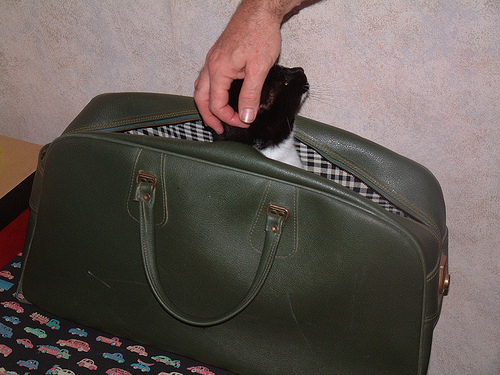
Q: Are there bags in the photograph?
A: Yes, there is a bag.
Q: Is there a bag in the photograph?
A: Yes, there is a bag.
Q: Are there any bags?
A: Yes, there is a bag.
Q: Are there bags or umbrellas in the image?
A: Yes, there is a bag.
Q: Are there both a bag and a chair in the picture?
A: No, there is a bag but no chairs.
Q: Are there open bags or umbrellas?
A: Yes, there is an open bag.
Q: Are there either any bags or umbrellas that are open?
A: Yes, the bag is open.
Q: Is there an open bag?
A: Yes, there is an open bag.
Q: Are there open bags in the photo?
A: Yes, there is an open bag.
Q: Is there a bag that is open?
A: Yes, there is a bag that is open.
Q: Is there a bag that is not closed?
A: Yes, there is a open bag.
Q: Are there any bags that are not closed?
A: Yes, there is a open bag.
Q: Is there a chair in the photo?
A: No, there are no chairs.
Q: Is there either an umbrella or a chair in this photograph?
A: No, there are no chairs or umbrellas.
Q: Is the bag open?
A: Yes, the bag is open.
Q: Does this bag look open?
A: Yes, the bag is open.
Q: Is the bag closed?
A: No, the bag is open.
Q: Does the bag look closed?
A: No, the bag is open.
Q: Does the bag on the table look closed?
A: No, the bag is open.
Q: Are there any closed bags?
A: No, there is a bag but it is open.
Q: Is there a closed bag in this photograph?
A: No, there is a bag but it is open.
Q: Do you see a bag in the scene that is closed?
A: No, there is a bag but it is open.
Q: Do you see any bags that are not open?
A: No, there is a bag but it is open.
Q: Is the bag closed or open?
A: The bag is open.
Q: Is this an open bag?
A: Yes, this is an open bag.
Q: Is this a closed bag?
A: No, this is an open bag.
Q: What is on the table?
A: The bag is on the table.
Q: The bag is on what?
A: The bag is on the table.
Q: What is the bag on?
A: The bag is on the table.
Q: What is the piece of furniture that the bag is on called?
A: The piece of furniture is a table.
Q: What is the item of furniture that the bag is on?
A: The piece of furniture is a table.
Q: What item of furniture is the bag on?
A: The bag is on the table.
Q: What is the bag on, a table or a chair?
A: The bag is on a table.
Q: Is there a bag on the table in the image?
A: Yes, there is a bag on the table.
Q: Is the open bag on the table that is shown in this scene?
A: Yes, the bag is on the table.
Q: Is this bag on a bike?
A: No, the bag is on the table.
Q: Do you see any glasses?
A: No, there are no glasses.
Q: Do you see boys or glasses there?
A: No, there are no glasses or boys.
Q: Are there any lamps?
A: No, there are no lamps.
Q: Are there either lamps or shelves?
A: No, there are no lamps or shelves.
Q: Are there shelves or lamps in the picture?
A: No, there are no lamps or shelves.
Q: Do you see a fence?
A: No, there are no fences.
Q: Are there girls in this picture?
A: No, there are no girls.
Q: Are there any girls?
A: No, there are no girls.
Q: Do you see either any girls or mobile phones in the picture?
A: No, there are no girls or mobile phones.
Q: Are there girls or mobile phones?
A: No, there are no girls or mobile phones.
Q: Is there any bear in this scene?
A: No, there are no bears.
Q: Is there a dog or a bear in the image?
A: No, there are no bears or dogs.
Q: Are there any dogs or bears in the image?
A: No, there are no bears or dogs.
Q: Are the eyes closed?
A: Yes, the eyes are closed.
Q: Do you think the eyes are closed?
A: Yes, the eyes are closed.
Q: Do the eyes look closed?
A: Yes, the eyes are closed.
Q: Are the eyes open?
A: No, the eyes are closed.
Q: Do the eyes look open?
A: No, the eyes are closed.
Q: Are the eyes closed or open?
A: The eyes are closed.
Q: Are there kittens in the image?
A: Yes, there is a kitten.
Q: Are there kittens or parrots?
A: Yes, there is a kitten.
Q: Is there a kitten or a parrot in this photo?
A: Yes, there is a kitten.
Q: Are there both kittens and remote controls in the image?
A: No, there is a kitten but no remote controls.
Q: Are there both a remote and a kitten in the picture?
A: No, there is a kitten but no remote controls.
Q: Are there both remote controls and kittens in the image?
A: No, there is a kitten but no remote controls.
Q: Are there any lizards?
A: No, there are no lizards.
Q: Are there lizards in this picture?
A: No, there are no lizards.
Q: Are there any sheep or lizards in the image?
A: No, there are no lizards or sheep.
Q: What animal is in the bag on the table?
A: The kitten is in the bag.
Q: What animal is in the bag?
A: The kitten is in the bag.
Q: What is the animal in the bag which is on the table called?
A: The animal is a kitten.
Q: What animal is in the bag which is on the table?
A: The animal is a kitten.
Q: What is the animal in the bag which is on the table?
A: The animal is a kitten.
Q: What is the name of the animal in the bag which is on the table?
A: The animal is a kitten.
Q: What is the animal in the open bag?
A: The animal is a kitten.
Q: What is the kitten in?
A: The kitten is in the bag.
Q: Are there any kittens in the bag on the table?
A: Yes, there is a kitten in the bag.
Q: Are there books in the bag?
A: No, there is a kitten in the bag.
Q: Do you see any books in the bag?
A: No, there is a kitten in the bag.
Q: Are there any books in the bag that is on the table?
A: No, there is a kitten in the bag.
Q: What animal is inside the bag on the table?
A: The kitten is inside the bag.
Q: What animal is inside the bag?
A: The kitten is inside the bag.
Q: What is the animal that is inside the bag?
A: The animal is a kitten.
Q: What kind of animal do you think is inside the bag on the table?
A: The animal is a kitten.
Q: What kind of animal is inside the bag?
A: The animal is a kitten.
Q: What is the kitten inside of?
A: The kitten is inside the bag.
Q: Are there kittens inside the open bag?
A: Yes, there is a kitten inside the bag.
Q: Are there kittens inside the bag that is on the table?
A: Yes, there is a kitten inside the bag.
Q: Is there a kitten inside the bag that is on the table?
A: Yes, there is a kitten inside the bag.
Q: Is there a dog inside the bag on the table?
A: No, there is a kitten inside the bag.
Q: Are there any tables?
A: Yes, there is a table.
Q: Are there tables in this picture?
A: Yes, there is a table.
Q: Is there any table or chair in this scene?
A: Yes, there is a table.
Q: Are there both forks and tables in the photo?
A: No, there is a table but no forks.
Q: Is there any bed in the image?
A: No, there are no beds.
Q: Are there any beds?
A: No, there are no beds.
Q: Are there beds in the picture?
A: No, there are no beds.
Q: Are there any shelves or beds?
A: No, there are no beds or shelves.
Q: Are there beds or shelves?
A: No, there are no beds or shelves.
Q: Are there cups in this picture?
A: No, there are no cups.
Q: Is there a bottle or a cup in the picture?
A: No, there are no cups or bottles.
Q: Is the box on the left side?
A: Yes, the box is on the left of the image.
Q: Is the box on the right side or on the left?
A: The box is on the left of the image.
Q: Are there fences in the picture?
A: No, there are no fences.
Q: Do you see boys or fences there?
A: No, there are no fences or boys.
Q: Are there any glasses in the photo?
A: No, there are no glasses.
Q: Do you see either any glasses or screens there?
A: No, there are no glasses or screens.